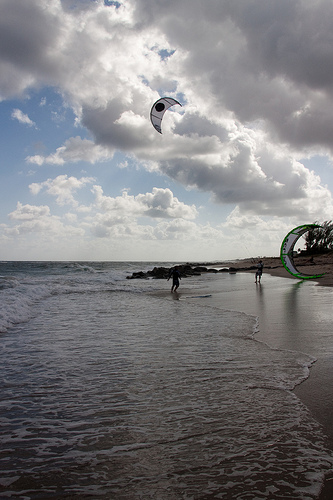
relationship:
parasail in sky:
[150, 95, 179, 136] [2, 3, 332, 263]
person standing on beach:
[250, 257, 265, 284] [153, 253, 331, 425]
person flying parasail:
[250, 257, 265, 284] [150, 95, 179, 136]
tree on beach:
[305, 216, 332, 260] [153, 253, 331, 425]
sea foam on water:
[43, 397, 169, 479] [3, 260, 314, 499]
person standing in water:
[167, 266, 186, 300] [3, 260, 314, 499]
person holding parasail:
[250, 257, 265, 284] [150, 95, 179, 136]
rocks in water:
[122, 257, 246, 283] [3, 260, 314, 499]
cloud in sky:
[128, 9, 319, 146] [2, 3, 332, 263]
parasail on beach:
[150, 95, 179, 136] [153, 253, 331, 425]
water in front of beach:
[3, 260, 314, 499] [153, 253, 331, 425]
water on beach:
[3, 260, 314, 499] [153, 253, 331, 425]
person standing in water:
[250, 257, 265, 284] [3, 260, 314, 499]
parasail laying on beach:
[150, 95, 179, 136] [153, 253, 331, 425]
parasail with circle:
[150, 95, 179, 136] [153, 100, 167, 114]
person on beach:
[250, 257, 265, 284] [153, 253, 331, 425]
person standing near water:
[250, 257, 265, 284] [3, 260, 314, 499]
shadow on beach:
[289, 278, 305, 297] [153, 253, 331, 425]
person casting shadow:
[250, 257, 265, 284] [289, 278, 305, 297]